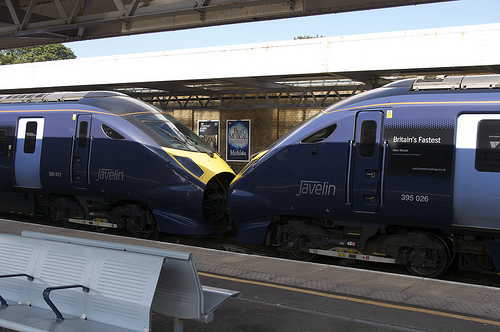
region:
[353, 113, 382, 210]
a door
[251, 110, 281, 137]
a brown wall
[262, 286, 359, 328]
the sidewalk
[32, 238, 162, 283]
a grey bench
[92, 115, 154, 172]
a shadow on the train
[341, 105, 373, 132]
light on the train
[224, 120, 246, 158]
a poster on the wall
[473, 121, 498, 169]
a window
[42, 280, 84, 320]
arm rest on the bench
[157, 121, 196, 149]
wipers on the train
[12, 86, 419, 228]
the train is blue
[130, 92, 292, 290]
the cars are connected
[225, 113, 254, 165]
white and blue sign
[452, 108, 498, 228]
the doors are white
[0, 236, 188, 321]
the bench is gray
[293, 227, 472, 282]
the tires are black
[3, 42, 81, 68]
the tree is green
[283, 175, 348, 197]
the train is called a javelin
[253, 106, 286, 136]
the building is made of brick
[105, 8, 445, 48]
the sky is clear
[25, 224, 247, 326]
A metal bench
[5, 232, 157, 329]
A metal bench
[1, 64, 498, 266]
A blue and yellow train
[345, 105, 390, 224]
Service door on the train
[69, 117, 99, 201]
Service door on the train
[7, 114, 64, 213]
passenger door on the train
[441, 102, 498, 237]
passenger door on the train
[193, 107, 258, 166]
Two posters on the wall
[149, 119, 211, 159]
windshield wipers on the train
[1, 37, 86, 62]
The top of a tree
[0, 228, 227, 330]
white metal benching beside train tracks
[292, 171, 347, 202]
white writing on side of train engine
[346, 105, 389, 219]
blue metal door on side of train engine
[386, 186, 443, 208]
white numbers on side of train engine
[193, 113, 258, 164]
posters hanging on wall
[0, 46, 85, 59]
trees with green leaves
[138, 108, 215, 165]
windshield on front of train engine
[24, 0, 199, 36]
large metal ceiling rafters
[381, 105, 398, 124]
yellow and white sticker on train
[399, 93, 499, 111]
yellow stripe on side of train engine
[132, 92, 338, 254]
Two trains facing each other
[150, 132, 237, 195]
The front yellow nose of a train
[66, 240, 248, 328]
A pair of metal seats back to back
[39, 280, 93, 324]
A black armrest of a seat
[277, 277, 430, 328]
A train platform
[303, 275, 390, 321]
A yellow line across the platform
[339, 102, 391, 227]
The side door of a train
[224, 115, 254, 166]
A poster on the wall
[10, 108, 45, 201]
A silver door on the train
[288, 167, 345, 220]
White inscription on a blue train